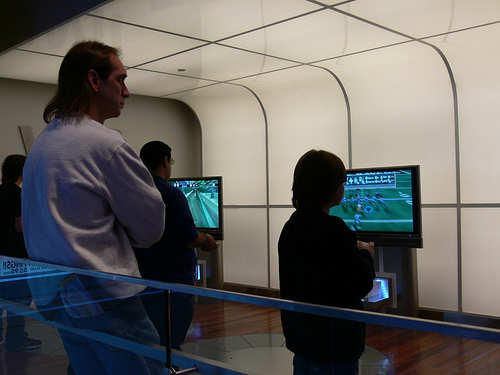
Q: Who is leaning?
A: A man.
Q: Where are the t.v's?
A: By the wall.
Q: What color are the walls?
A: White.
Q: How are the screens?
A: On.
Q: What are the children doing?
A: Playing a game.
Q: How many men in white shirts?
A: One.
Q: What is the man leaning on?
A: Table.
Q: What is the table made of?
A: Glass.